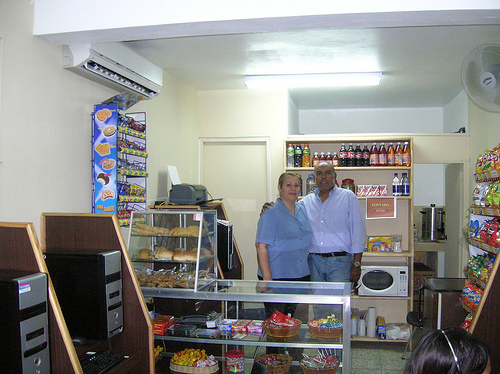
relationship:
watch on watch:
[351, 258, 363, 268] [351, 261, 363, 268]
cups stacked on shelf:
[356, 305, 378, 338] [353, 241, 411, 371]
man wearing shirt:
[259, 158, 364, 317] [297, 178, 371, 253]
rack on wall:
[73, 93, 160, 221] [17, 23, 172, 313]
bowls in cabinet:
[364, 311, 415, 349] [113, 270, 429, 369]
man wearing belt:
[259, 161, 366, 364] [309, 247, 348, 257]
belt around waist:
[309, 247, 348, 257] [305, 240, 358, 264]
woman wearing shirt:
[256, 172, 317, 292] [257, 197, 313, 279]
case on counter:
[125, 207, 215, 294] [135, 275, 354, 305]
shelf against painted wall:
[95, 102, 146, 229] [0, 0, 198, 247]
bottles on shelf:
[285, 140, 409, 165] [284, 161, 413, 171]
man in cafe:
[259, 161, 366, 364] [2, 0, 497, 372]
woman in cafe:
[257, 171, 316, 355] [2, 0, 497, 372]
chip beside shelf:
[464, 217, 479, 237] [451, 294, 476, 321]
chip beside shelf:
[470, 184, 482, 207] [462, 230, 498, 257]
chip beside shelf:
[474, 153, 484, 178] [465, 201, 498, 216]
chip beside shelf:
[460, 280, 471, 299] [473, 165, 498, 184]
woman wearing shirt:
[257, 171, 316, 355] [262, 203, 331, 292]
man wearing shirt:
[259, 161, 366, 364] [301, 192, 368, 254]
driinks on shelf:
[402, 140, 411, 166] [281, 126, 408, 343]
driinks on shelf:
[465, 152, 496, 298] [281, 126, 408, 343]